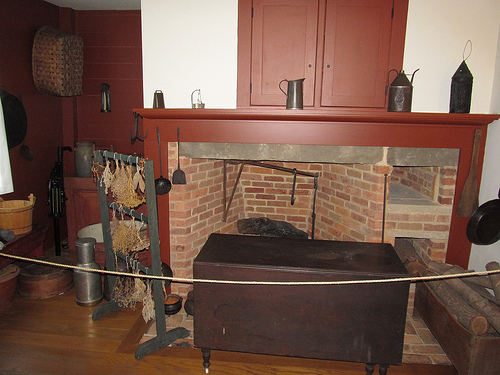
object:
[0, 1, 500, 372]
wall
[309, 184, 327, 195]
rack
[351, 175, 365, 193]
hole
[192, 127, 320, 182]
rack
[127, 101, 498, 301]
mantle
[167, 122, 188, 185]
tool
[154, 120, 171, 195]
tool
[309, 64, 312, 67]
dot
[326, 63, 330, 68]
dot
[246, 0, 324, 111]
cabinet door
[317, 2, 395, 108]
cabinet door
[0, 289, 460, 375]
floor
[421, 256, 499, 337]
firewood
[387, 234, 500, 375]
container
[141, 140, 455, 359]
brick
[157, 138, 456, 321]
fireplace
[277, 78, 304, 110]
container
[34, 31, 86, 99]
basket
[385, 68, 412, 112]
jar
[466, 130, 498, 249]
paddle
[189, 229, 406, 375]
box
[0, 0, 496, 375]
display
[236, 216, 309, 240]
log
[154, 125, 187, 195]
cooking utensils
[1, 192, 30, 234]
basket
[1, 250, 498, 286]
rope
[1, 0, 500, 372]
exhibit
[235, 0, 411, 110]
cabinets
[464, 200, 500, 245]
frying pan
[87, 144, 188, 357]
drying rack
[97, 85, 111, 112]
lantern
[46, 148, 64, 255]
water pump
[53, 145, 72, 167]
handle